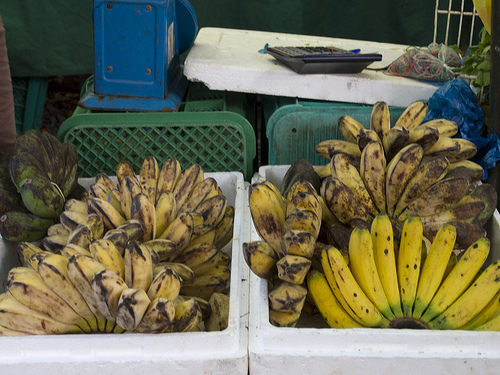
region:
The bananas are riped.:
[64, 183, 217, 331]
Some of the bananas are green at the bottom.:
[372, 301, 452, 326]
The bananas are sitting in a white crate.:
[55, 196, 485, 372]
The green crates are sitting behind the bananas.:
[59, 103, 256, 153]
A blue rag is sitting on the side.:
[423, 83, 495, 160]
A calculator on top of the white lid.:
[255, 28, 398, 95]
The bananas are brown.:
[311, 139, 498, 252]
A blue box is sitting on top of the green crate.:
[84, 8, 190, 142]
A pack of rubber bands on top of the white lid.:
[395, 38, 475, 83]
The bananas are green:
[23, 136, 59, 221]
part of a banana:
[376, 249, 396, 278]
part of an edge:
[223, 302, 253, 345]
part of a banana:
[314, 238, 339, 267]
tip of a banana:
[115, 226, 151, 261]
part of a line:
[233, 306, 261, 357]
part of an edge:
[324, 327, 386, 369]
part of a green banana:
[28, 182, 48, 203]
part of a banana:
[159, 243, 209, 291]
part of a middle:
[232, 306, 255, 350]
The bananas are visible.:
[277, 106, 461, 364]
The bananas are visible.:
[315, 176, 400, 313]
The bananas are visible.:
[289, 131, 390, 295]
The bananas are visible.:
[296, 82, 439, 280]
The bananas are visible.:
[324, 204, 426, 369]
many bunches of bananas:
[17, 157, 204, 347]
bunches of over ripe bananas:
[320, 100, 482, 220]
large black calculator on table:
[266, 37, 386, 77]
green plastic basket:
[70, 99, 247, 181]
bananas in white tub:
[250, 160, 415, 372]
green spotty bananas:
[0, 132, 77, 220]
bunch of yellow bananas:
[330, 208, 499, 338]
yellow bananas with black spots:
[372, 219, 431, 314]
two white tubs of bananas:
[44, 136, 494, 366]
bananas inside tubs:
[59, 142, 485, 370]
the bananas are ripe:
[292, 209, 491, 329]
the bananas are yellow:
[269, 223, 487, 325]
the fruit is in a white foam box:
[245, 137, 495, 373]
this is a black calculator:
[258, 30, 386, 80]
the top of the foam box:
[185, 21, 498, 102]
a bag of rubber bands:
[383, 27, 460, 80]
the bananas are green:
[1, 125, 64, 225]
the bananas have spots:
[344, 217, 470, 267]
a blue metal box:
[68, 0, 181, 107]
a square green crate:
[37, 97, 260, 174]